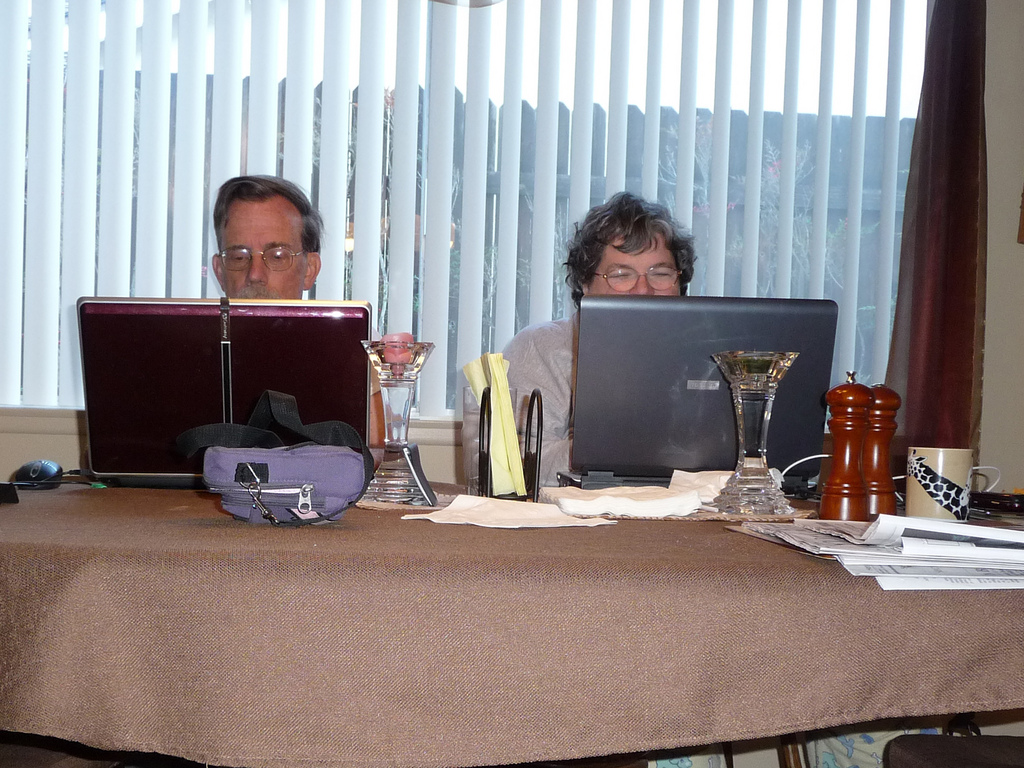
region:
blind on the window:
[785, 266, 808, 290]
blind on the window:
[725, 256, 760, 291]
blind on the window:
[525, 281, 549, 326]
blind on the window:
[323, 263, 346, 295]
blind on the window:
[8, 363, 25, 402]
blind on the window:
[89, 265, 127, 294]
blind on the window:
[408, 373, 448, 430]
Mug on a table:
[893, 435, 993, 530]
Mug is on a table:
[889, 434, 984, 529]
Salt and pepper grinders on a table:
[814, 358, 904, 529]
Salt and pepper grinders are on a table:
[806, 362, 905, 536]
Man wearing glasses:
[201, 231, 325, 277]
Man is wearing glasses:
[203, 238, 330, 277]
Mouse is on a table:
[10, 438, 74, 496]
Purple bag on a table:
[179, 378, 401, 543]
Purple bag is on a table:
[190, 375, 391, 532]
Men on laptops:
[51, 156, 852, 517]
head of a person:
[499, 171, 756, 372]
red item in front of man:
[0, 257, 421, 529]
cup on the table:
[843, 402, 999, 564]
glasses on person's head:
[517, 184, 783, 339]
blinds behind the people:
[22, 10, 741, 146]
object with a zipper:
[166, 402, 392, 577]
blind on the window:
[814, 275, 853, 299]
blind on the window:
[773, 271, 824, 294]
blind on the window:
[526, 290, 558, 317]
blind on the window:
[472, 325, 498, 358]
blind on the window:
[393, 293, 429, 328]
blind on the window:
[348, 281, 383, 301]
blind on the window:
[95, 272, 127, 288]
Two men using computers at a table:
[76, 172, 839, 505]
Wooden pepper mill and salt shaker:
[822, 365, 900, 530]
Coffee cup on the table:
[901, 435, 991, 528]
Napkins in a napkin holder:
[470, 338, 544, 506]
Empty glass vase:
[710, 338, 803, 534]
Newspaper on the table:
[730, 504, 1022, 596]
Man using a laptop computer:
[493, 189, 838, 502]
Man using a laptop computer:
[75, 174, 374, 523]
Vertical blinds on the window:
[0, 0, 936, 433]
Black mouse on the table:
[12, 451, 63, 493]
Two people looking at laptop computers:
[65, 156, 849, 489]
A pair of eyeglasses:
[574, 247, 691, 299]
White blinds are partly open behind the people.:
[18, 6, 913, 434]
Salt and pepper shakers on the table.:
[821, 370, 901, 536]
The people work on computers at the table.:
[72, 165, 856, 507]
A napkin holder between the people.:
[464, 348, 554, 519]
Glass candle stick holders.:
[362, 328, 806, 528]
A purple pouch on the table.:
[193, 395, 383, 535]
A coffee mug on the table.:
[907, 433, 1006, 523]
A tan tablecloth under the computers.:
[6, 477, 1019, 740]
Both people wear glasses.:
[199, 228, 683, 315]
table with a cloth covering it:
[0, 469, 1021, 765]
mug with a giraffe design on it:
[903, 442, 979, 522]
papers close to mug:
[724, 447, 1022, 593]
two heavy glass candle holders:
[354, 331, 797, 525]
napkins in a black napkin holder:
[461, 350, 545, 505]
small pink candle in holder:
[356, 331, 439, 509]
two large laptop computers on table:
[2, 296, 1023, 765]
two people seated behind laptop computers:
[5, 175, 1023, 767]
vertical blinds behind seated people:
[0, 2, 978, 765]